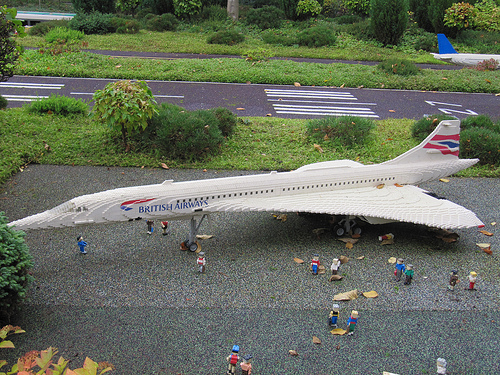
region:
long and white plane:
[64, 97, 494, 255]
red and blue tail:
[435, 120, 463, 161]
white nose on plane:
[4, 193, 92, 228]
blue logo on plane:
[150, 188, 217, 243]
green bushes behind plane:
[48, 64, 268, 148]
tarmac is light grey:
[105, 250, 202, 362]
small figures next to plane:
[51, 211, 485, 372]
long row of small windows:
[142, 165, 387, 229]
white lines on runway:
[0, 44, 467, 131]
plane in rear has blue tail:
[415, 38, 460, 69]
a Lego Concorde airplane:
[9, 118, 484, 230]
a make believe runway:
[7, 77, 498, 124]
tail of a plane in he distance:
[430, 35, 499, 69]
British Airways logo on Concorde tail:
[430, 131, 458, 155]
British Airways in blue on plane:
[137, 198, 212, 214]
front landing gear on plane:
[184, 216, 202, 250]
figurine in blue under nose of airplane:
[73, 235, 88, 254]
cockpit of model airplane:
[52, 200, 89, 214]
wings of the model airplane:
[202, 159, 484, 229]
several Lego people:
[75, 221, 475, 371]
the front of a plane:
[42, 179, 102, 242]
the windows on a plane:
[143, 169, 268, 225]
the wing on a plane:
[200, 134, 456, 259]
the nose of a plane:
[26, 180, 101, 255]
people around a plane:
[222, 197, 422, 362]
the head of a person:
[389, 255, 416, 280]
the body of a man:
[302, 245, 338, 281]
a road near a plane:
[179, 36, 330, 210]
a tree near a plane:
[83, 72, 202, 184]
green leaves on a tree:
[65, 28, 216, 157]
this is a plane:
[88, 135, 468, 249]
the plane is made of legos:
[300, 129, 382, 247]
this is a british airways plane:
[78, 192, 330, 216]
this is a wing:
[233, 180, 438, 257]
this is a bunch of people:
[215, 287, 430, 347]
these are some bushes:
[111, 108, 294, 138]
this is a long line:
[88, 72, 125, 97]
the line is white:
[66, 82, 74, 102]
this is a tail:
[338, 143, 488, 231]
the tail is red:
[391, 125, 490, 153]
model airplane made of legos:
[6, 106, 476, 270]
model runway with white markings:
[8, 63, 495, 137]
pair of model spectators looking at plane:
[322, 299, 368, 341]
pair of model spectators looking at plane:
[388, 255, 421, 292]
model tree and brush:
[89, 81, 236, 160]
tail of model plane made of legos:
[430, 27, 496, 79]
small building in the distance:
[12, 4, 77, 39]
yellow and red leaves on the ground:
[1, 313, 112, 368]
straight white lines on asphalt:
[257, 75, 380, 130]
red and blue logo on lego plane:
[109, 190, 216, 223]